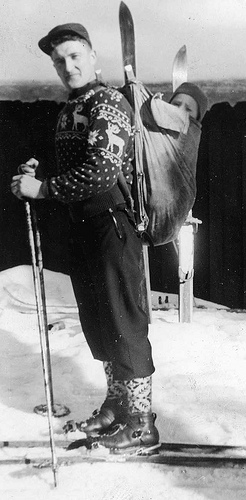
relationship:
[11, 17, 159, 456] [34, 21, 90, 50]
man wearing hat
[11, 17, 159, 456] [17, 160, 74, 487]
man holding poles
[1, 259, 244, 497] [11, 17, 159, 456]
snow under man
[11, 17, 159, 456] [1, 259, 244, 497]
man standing in snow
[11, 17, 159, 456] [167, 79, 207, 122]
man with baby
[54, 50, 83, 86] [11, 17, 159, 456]
face of man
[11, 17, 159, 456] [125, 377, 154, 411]
man wearing sock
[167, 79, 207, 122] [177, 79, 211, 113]
baby wearing cap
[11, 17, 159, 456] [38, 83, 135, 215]
man wearing sweater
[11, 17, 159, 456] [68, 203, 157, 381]
man wearing pants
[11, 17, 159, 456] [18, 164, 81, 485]
man holding ski poles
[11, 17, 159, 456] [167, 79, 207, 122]
man carrying baby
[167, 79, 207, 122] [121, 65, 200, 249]
baby in a knapsack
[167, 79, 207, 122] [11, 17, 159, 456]
baby behind man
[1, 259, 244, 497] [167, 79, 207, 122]
snow under baby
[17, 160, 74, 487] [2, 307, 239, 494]
skis in snow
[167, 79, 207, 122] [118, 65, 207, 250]
baby in knapsack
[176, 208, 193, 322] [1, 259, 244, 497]
object in snow